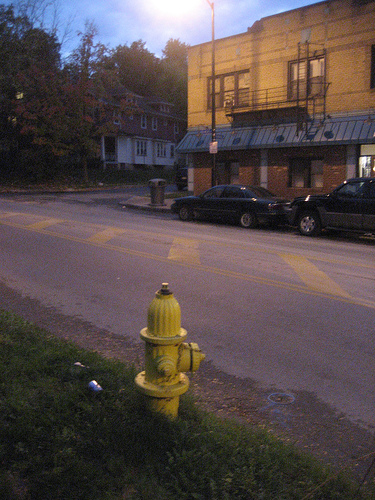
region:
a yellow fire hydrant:
[130, 279, 207, 445]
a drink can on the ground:
[73, 370, 113, 409]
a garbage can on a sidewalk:
[145, 167, 167, 216]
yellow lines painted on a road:
[31, 218, 364, 294]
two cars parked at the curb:
[170, 168, 370, 232]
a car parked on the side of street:
[166, 178, 292, 234]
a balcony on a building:
[219, 57, 339, 129]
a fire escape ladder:
[291, 31, 331, 148]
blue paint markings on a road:
[249, 382, 324, 432]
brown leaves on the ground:
[30, 174, 129, 199]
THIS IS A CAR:
[163, 176, 292, 231]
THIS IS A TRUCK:
[278, 163, 374, 250]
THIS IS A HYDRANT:
[126, 278, 214, 432]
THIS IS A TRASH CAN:
[141, 170, 172, 217]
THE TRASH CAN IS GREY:
[141, 171, 172, 213]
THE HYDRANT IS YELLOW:
[119, 273, 213, 442]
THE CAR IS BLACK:
[167, 179, 292, 236]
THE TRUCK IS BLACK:
[284, 168, 374, 247]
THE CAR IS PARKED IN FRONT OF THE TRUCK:
[171, 179, 294, 233]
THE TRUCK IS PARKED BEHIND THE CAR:
[282, 168, 374, 243]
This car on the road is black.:
[170, 180, 290, 226]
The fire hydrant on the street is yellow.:
[134, 282, 198, 413]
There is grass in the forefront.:
[57, 417, 148, 459]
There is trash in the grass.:
[73, 356, 104, 404]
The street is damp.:
[235, 387, 330, 439]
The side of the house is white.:
[121, 143, 167, 159]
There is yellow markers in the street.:
[91, 223, 224, 262]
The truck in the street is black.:
[285, 177, 374, 236]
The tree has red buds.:
[17, 66, 116, 165]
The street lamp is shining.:
[149, 3, 215, 25]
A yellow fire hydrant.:
[133, 281, 207, 421]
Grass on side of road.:
[0, 310, 374, 495]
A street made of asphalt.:
[1, 182, 372, 497]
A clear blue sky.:
[1, 0, 326, 79]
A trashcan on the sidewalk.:
[148, 178, 167, 209]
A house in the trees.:
[55, 76, 188, 173]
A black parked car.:
[169, 182, 291, 227]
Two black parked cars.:
[169, 175, 373, 243]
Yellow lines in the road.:
[0, 209, 372, 309]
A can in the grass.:
[87, 378, 103, 391]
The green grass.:
[0, 309, 373, 498]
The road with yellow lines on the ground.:
[3, 184, 373, 499]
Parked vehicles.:
[166, 171, 373, 239]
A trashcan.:
[149, 175, 166, 209]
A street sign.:
[207, 140, 218, 154]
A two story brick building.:
[186, 0, 373, 205]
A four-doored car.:
[170, 182, 290, 233]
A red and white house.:
[88, 83, 183, 173]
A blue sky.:
[2, 0, 323, 78]